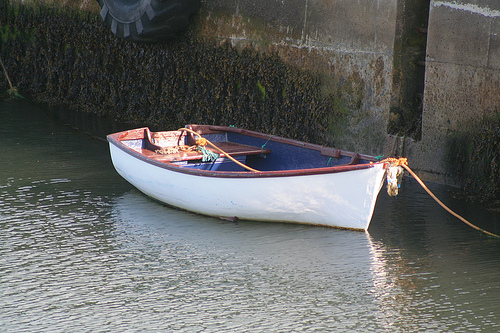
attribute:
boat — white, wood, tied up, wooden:
[106, 123, 393, 232]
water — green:
[0, 99, 498, 332]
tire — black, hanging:
[95, 0, 201, 42]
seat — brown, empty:
[130, 140, 269, 164]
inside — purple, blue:
[123, 132, 375, 173]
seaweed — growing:
[1, 1, 325, 145]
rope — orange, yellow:
[175, 127, 499, 240]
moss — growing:
[475, 224, 499, 240]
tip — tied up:
[363, 152, 393, 232]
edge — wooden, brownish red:
[106, 124, 389, 178]